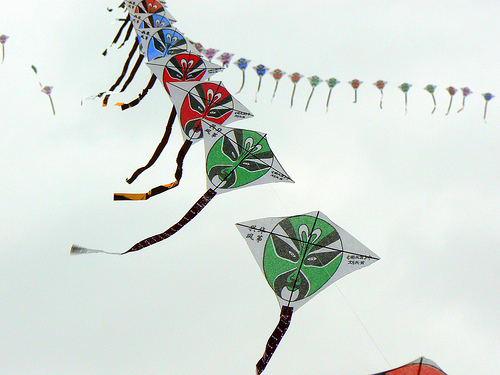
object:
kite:
[221, 207, 381, 373]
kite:
[165, 79, 256, 144]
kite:
[132, 26, 205, 65]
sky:
[0, 3, 497, 374]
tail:
[70, 189, 222, 255]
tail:
[113, 140, 194, 201]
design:
[262, 213, 345, 306]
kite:
[367, 355, 457, 375]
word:
[256, 233, 265, 243]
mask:
[149, 27, 190, 62]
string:
[37, 81, 48, 89]